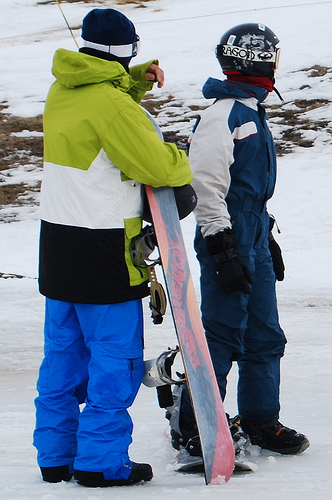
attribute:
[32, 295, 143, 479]
pants — light blue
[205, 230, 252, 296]
gloves — black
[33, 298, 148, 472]
snot pants — blue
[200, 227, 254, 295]
gloves — black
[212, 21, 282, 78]
helmet — black